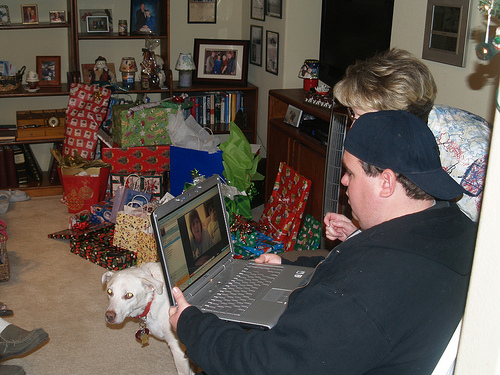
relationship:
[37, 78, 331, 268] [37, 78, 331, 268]
gifts in gifts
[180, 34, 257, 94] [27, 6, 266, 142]
frame on shelf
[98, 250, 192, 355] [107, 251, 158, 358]
dog wears collar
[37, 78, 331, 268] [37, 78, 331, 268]
gifts on gifts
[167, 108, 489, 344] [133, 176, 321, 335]
cap holding laptop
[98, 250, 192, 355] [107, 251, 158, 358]
dog wear collar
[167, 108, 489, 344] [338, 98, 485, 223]
cap wears cap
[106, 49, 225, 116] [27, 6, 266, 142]
lamp on shelf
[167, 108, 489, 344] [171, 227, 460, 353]
cap in sweatshirt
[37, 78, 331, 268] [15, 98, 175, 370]
gifts on floor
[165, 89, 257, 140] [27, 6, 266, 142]
books on shelf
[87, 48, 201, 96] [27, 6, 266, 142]
decorations on shelf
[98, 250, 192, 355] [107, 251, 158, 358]
dog has collar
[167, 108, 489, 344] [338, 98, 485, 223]
cap wear cap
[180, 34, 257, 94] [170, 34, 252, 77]
frame in frame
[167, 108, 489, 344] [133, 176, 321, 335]
cap holds laptop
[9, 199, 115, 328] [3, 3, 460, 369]
carpet in livingroom